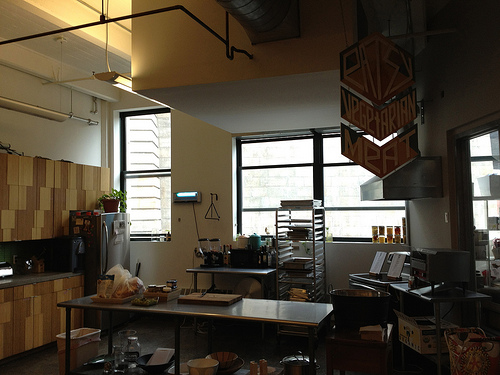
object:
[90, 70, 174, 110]
light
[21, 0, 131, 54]
ceiling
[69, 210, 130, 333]
icebox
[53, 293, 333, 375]
table